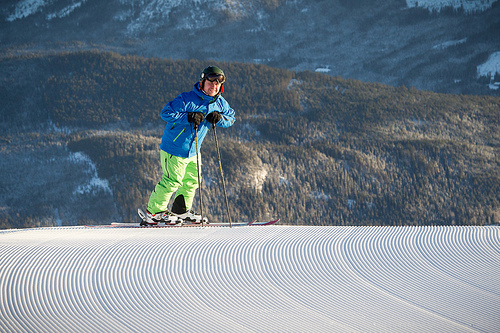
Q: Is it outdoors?
A: Yes, it is outdoors.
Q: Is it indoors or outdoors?
A: It is outdoors.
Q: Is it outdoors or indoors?
A: It is outdoors.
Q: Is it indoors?
A: No, it is outdoors.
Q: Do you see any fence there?
A: No, there are no fences.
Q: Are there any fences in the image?
A: No, there are no fences.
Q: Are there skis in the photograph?
A: Yes, there are skis.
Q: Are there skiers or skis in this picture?
A: Yes, there are skis.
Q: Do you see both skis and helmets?
A: Yes, there are both skis and a helmet.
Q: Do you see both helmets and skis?
A: Yes, there are both skis and a helmet.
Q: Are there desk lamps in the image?
A: No, there are no desk lamps.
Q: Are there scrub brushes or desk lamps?
A: No, there are no desk lamps or scrub brushes.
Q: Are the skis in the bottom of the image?
A: Yes, the skis are in the bottom of the image.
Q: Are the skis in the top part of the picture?
A: No, the skis are in the bottom of the image.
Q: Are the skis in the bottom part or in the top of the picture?
A: The skis are in the bottom of the image.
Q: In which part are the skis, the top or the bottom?
A: The skis are in the bottom of the image.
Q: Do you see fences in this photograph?
A: No, there are no fences.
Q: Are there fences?
A: No, there are no fences.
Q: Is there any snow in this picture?
A: Yes, there is snow.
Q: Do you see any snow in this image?
A: Yes, there is snow.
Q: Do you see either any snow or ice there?
A: Yes, there is snow.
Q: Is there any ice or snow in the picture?
A: Yes, there is snow.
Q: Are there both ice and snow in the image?
A: No, there is snow but no ice.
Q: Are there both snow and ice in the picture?
A: No, there is snow but no ice.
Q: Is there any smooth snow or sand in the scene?
A: Yes, there is smooth snow.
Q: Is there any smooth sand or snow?
A: Yes, there is smooth snow.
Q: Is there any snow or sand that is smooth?
A: Yes, the snow is smooth.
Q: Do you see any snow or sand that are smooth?
A: Yes, the snow is smooth.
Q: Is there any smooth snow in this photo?
A: Yes, there is smooth snow.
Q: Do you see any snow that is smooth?
A: Yes, there is smooth snow.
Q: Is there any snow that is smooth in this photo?
A: Yes, there is smooth snow.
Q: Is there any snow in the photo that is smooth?
A: Yes, there is snow that is smooth.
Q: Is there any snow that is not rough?
A: Yes, there is smooth snow.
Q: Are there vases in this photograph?
A: No, there are no vases.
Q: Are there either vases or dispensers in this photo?
A: No, there are no vases or dispensers.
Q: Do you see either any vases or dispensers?
A: No, there are no vases or dispensers.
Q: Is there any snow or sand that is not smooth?
A: No, there is snow but it is smooth.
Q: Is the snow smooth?
A: Yes, the snow is smooth.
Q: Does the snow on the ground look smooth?
A: Yes, the snow is smooth.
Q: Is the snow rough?
A: No, the snow is smooth.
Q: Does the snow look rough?
A: No, the snow is smooth.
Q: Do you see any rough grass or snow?
A: No, there is snow but it is smooth.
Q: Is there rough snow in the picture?
A: No, there is snow but it is smooth.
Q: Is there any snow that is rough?
A: No, there is snow but it is smooth.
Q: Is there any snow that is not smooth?
A: No, there is snow but it is smooth.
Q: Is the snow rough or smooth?
A: The snow is smooth.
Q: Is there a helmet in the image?
A: Yes, there is a helmet.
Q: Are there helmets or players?
A: Yes, there is a helmet.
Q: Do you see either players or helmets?
A: Yes, there is a helmet.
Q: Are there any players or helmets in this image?
A: Yes, there is a helmet.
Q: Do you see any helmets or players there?
A: Yes, there is a helmet.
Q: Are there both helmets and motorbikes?
A: No, there is a helmet but no motorcycles.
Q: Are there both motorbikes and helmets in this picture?
A: No, there is a helmet but no motorcycles.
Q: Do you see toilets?
A: No, there are no toilets.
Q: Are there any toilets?
A: No, there are no toilets.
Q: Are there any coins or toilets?
A: No, there are no toilets or coins.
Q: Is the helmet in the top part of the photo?
A: Yes, the helmet is in the top of the image.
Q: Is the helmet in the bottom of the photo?
A: No, the helmet is in the top of the image.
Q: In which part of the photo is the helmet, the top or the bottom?
A: The helmet is in the top of the image.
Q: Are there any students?
A: No, there are no students.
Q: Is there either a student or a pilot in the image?
A: No, there are no students or pilots.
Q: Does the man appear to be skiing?
A: Yes, the man is skiing.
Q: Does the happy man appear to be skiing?
A: Yes, the man is skiing.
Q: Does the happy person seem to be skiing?
A: Yes, the man is skiing.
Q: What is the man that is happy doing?
A: The man is skiing.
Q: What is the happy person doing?
A: The man is skiing.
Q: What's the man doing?
A: The man is skiing.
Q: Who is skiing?
A: The man is skiing.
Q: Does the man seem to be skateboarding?
A: No, the man is skiing.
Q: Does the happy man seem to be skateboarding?
A: No, the man is skiing.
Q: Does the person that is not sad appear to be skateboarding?
A: No, the man is skiing.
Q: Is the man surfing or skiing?
A: The man is skiing.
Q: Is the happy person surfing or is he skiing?
A: The man is skiing.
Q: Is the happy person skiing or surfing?
A: The man is skiing.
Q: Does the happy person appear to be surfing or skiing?
A: The man is skiing.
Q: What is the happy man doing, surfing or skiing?
A: The man is skiing.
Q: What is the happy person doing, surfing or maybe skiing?
A: The man is skiing.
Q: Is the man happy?
A: Yes, the man is happy.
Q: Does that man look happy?
A: Yes, the man is happy.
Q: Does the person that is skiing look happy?
A: Yes, the man is happy.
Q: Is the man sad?
A: No, the man is happy.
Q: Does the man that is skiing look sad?
A: No, the man is happy.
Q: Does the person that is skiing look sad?
A: No, the man is happy.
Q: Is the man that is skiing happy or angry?
A: The man is happy.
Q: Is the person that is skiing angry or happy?
A: The man is happy.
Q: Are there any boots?
A: Yes, there are boots.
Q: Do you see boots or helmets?
A: Yes, there are boots.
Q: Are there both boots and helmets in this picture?
A: Yes, there are both boots and a helmet.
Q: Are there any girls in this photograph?
A: No, there are no girls.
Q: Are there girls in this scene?
A: No, there are no girls.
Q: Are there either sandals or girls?
A: No, there are no girls or sandals.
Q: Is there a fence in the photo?
A: No, there are no fences.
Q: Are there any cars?
A: No, there are no cars.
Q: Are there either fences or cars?
A: No, there are no cars or fences.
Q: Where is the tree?
A: The tree is on the hill.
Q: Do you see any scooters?
A: No, there are no scooters.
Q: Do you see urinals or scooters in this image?
A: No, there are no scooters or urinals.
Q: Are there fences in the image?
A: No, there are no fences.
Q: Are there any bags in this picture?
A: No, there are no bags.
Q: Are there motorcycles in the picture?
A: No, there are no motorcycles.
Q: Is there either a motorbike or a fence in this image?
A: No, there are no motorcycles or fences.